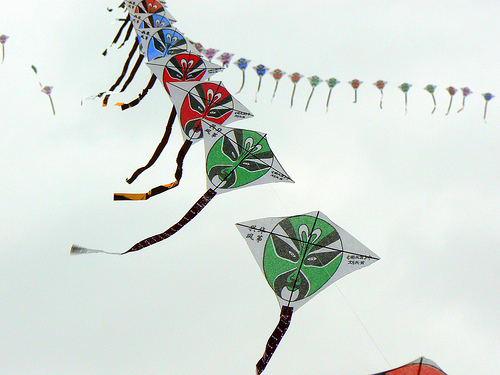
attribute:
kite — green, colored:
[221, 207, 381, 373]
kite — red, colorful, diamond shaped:
[157, 78, 258, 149]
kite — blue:
[132, 22, 201, 83]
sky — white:
[0, 3, 497, 374]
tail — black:
[70, 189, 222, 259]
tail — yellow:
[110, 140, 194, 206]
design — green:
[262, 213, 345, 306]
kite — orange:
[367, 352, 457, 375]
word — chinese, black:
[343, 249, 375, 269]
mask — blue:
[149, 27, 190, 62]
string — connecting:
[32, 72, 45, 89]